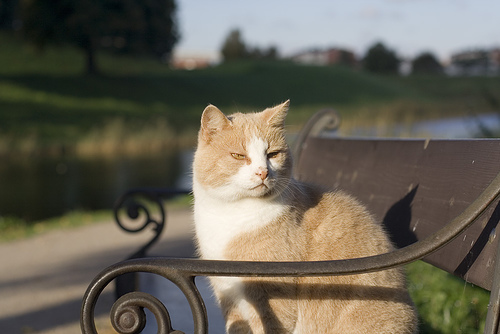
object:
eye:
[226, 150, 249, 163]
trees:
[221, 25, 279, 59]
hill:
[185, 54, 408, 117]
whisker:
[273, 178, 311, 207]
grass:
[423, 286, 472, 327]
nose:
[250, 162, 270, 181]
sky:
[174, 1, 496, 56]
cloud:
[357, 6, 381, 23]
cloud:
[184, 9, 213, 45]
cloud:
[359, 25, 380, 39]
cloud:
[453, 2, 468, 20]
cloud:
[266, 19, 297, 37]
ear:
[262, 99, 292, 127]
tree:
[0, 0, 180, 72]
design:
[77, 189, 210, 334]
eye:
[266, 149, 283, 160]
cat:
[186, 98, 420, 334]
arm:
[79, 256, 208, 334]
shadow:
[221, 278, 412, 334]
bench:
[78, 110, 500, 334]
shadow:
[380, 183, 420, 250]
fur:
[321, 206, 366, 238]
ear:
[201, 103, 233, 136]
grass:
[133, 75, 329, 100]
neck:
[192, 195, 289, 222]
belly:
[200, 232, 268, 334]